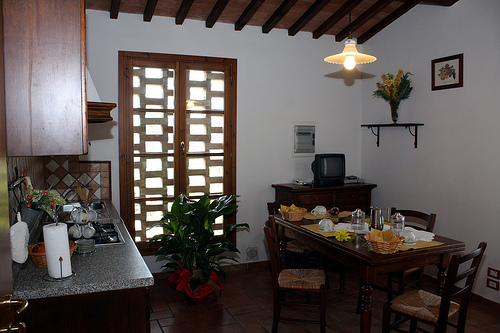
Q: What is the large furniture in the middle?
A: Table.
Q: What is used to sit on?
A: A chair.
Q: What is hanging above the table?
A: A light.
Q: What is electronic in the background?
A: A television.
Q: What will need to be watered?
A: The plant.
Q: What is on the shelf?
A: Flowers.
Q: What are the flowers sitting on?
A: A shelf.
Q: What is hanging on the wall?
A: A picture.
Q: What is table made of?
A: Wood.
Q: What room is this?
A: Kitchen.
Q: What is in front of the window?
A: A plant.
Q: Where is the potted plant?
A: In front of the window.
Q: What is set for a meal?
A: The table.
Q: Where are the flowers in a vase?
A: On a small shelf on the right wall.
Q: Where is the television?
A: On the bureau in the corner.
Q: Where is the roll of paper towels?
A: On the counter.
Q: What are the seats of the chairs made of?
A: Wicker.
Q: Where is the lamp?
A: Hanging above the table.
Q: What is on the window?
A: Slats of wood.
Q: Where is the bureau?
A: In the corner.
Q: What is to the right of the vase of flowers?
A: A picture.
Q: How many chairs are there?
A: Four.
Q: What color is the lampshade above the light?
A: Yellow.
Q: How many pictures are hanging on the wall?
A: One.